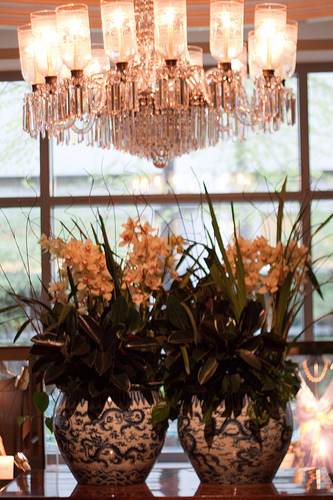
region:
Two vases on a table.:
[41, 342, 302, 486]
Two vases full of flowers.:
[21, 201, 311, 486]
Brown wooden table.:
[3, 456, 332, 497]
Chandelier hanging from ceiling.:
[9, 0, 309, 184]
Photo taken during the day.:
[3, 79, 331, 384]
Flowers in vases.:
[8, 185, 302, 418]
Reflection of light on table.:
[3, 454, 326, 493]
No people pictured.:
[3, 140, 330, 493]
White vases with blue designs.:
[46, 380, 314, 498]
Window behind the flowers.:
[0, 71, 329, 352]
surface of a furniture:
[170, 474, 199, 491]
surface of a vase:
[197, 425, 252, 470]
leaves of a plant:
[176, 343, 243, 398]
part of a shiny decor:
[296, 403, 322, 447]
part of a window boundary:
[169, 186, 248, 211]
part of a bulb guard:
[75, 79, 182, 135]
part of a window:
[241, 138, 272, 169]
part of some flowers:
[235, 227, 274, 283]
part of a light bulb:
[261, 3, 289, 53]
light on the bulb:
[151, 7, 165, 46]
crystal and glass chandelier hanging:
[8, 0, 303, 166]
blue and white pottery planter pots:
[49, 341, 304, 493]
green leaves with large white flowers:
[0, 169, 331, 455]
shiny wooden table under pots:
[6, 451, 331, 497]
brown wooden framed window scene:
[3, 49, 332, 484]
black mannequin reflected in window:
[288, 342, 331, 487]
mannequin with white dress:
[294, 351, 332, 472]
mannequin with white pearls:
[292, 352, 331, 481]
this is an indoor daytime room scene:
[2, 0, 329, 495]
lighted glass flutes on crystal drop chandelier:
[11, 0, 304, 87]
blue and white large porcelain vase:
[52, 389, 169, 486]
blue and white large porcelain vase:
[176, 385, 296, 483]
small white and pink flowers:
[40, 234, 115, 306]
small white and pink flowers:
[118, 215, 182, 310]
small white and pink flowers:
[223, 230, 306, 302]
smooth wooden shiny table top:
[0, 464, 328, 499]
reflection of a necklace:
[302, 358, 331, 381]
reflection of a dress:
[291, 368, 331, 468]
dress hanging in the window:
[0, 374, 35, 464]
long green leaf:
[201, 179, 245, 315]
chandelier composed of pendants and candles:
[7, 7, 307, 168]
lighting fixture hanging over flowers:
[20, 11, 285, 345]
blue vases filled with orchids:
[32, 343, 298, 488]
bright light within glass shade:
[13, 5, 295, 81]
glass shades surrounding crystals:
[15, 4, 297, 67]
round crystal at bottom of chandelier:
[143, 144, 181, 172]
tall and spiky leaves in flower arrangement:
[40, 202, 289, 350]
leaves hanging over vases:
[22, 342, 295, 438]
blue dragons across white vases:
[79, 410, 278, 471]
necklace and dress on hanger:
[285, 356, 329, 481]